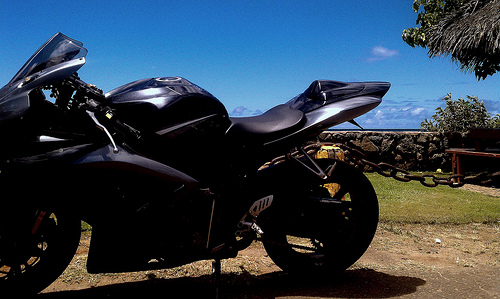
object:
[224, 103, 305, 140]
seat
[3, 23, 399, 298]
engine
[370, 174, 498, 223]
grass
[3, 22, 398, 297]
bike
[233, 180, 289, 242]
metal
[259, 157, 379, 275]
wheelplayer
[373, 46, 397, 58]
cloud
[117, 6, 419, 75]
sky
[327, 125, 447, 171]
wall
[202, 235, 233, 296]
stand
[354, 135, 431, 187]
chain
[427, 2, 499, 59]
thatch roof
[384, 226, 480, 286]
floor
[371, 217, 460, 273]
person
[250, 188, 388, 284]
wheel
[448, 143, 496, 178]
table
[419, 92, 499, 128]
bush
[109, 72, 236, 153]
gas tank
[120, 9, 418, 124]
outside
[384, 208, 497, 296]
ground